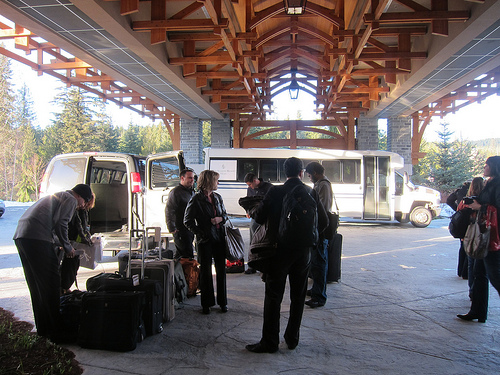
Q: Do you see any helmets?
A: No, there are no helmets.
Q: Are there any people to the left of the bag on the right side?
A: Yes, there is a person to the left of the bag.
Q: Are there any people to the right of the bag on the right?
A: No, the person is to the left of the bag.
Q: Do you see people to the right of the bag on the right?
A: No, the person is to the left of the bag.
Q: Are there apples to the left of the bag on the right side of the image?
A: No, there is a person to the left of the bag.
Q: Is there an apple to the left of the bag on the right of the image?
A: No, there is a person to the left of the bag.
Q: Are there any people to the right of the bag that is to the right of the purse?
A: Yes, there is a person to the right of the backpack.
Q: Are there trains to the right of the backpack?
A: No, there is a person to the right of the backpack.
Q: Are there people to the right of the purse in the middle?
A: Yes, there is a person to the right of the purse.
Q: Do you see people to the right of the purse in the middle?
A: Yes, there is a person to the right of the purse.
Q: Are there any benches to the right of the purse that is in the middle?
A: No, there is a person to the right of the purse.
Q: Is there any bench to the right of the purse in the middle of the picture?
A: No, there is a person to the right of the purse.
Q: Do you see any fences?
A: No, there are no fences.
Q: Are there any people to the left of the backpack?
A: Yes, there is a person to the left of the backpack.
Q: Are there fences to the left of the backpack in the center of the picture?
A: No, there is a person to the left of the backpack.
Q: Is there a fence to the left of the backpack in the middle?
A: No, there is a person to the left of the backpack.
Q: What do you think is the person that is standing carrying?
A: The person is carrying a purse.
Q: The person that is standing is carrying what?
A: The person is carrying a purse.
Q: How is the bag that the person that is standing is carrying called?
A: The bag is a purse.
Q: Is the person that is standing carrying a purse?
A: Yes, the person is carrying a purse.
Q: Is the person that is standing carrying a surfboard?
A: No, the person is carrying a purse.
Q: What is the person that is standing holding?
A: The person is holding the purse.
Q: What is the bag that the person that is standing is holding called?
A: The bag is a purse.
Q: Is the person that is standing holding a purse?
A: Yes, the person is holding a purse.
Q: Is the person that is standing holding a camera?
A: No, the person is holding a purse.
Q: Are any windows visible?
A: Yes, there is a window.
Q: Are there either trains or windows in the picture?
A: Yes, there is a window.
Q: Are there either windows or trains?
A: Yes, there is a window.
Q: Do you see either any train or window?
A: Yes, there is a window.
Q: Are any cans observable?
A: No, there are no cans.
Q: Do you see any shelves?
A: No, there are no shelves.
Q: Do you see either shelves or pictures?
A: No, there are no shelves or pictures.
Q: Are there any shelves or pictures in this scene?
A: No, there are no shelves or pictures.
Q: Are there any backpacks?
A: Yes, there is a backpack.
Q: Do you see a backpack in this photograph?
A: Yes, there is a backpack.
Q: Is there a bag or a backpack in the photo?
A: Yes, there is a backpack.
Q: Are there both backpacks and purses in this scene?
A: Yes, there are both a backpack and a purse.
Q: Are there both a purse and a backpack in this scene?
A: Yes, there are both a backpack and a purse.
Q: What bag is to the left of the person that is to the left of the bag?
A: The bag is a backpack.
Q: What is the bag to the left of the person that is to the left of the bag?
A: The bag is a backpack.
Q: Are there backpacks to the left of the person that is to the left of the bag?
A: Yes, there is a backpack to the left of the person.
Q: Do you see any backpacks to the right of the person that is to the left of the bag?
A: No, the backpack is to the left of the person.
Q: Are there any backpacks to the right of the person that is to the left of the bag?
A: No, the backpack is to the left of the person.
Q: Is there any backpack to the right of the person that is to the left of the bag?
A: No, the backpack is to the left of the person.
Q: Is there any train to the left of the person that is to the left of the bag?
A: No, there is a backpack to the left of the person.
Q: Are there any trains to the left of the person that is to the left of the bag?
A: No, there is a backpack to the left of the person.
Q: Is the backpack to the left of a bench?
A: No, the backpack is to the left of the person.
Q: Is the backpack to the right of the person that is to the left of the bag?
A: No, the backpack is to the left of the person.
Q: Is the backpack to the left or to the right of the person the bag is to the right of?
A: The backpack is to the left of the person.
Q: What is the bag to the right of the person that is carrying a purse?
A: The bag is a backpack.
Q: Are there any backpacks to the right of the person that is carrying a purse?
A: Yes, there is a backpack to the right of the person.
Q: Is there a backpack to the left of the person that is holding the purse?
A: No, the backpack is to the right of the person.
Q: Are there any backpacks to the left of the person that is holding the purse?
A: No, the backpack is to the right of the person.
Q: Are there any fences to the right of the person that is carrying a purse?
A: No, there is a backpack to the right of the person.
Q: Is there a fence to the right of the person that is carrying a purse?
A: No, there is a backpack to the right of the person.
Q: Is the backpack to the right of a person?
A: Yes, the backpack is to the right of a person.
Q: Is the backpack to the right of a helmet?
A: No, the backpack is to the right of a person.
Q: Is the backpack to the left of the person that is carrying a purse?
A: No, the backpack is to the right of the person.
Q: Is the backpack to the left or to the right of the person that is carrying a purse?
A: The backpack is to the right of the person.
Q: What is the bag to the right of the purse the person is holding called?
A: The bag is a backpack.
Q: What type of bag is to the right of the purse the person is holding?
A: The bag is a backpack.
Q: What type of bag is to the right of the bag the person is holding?
A: The bag is a backpack.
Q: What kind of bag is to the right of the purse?
A: The bag is a backpack.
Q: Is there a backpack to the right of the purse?
A: Yes, there is a backpack to the right of the purse.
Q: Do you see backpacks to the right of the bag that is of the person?
A: Yes, there is a backpack to the right of the purse.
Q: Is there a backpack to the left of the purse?
A: No, the backpack is to the right of the purse.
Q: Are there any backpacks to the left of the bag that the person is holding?
A: No, the backpack is to the right of the purse.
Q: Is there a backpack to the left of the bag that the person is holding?
A: No, the backpack is to the right of the purse.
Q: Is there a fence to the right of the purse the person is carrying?
A: No, there is a backpack to the right of the purse.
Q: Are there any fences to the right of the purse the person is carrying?
A: No, there is a backpack to the right of the purse.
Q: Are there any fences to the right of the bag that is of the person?
A: No, there is a backpack to the right of the purse.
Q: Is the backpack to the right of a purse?
A: Yes, the backpack is to the right of a purse.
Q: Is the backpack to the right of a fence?
A: No, the backpack is to the right of a purse.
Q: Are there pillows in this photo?
A: No, there are no pillows.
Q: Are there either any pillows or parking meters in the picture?
A: No, there are no pillows or parking meters.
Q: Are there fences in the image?
A: No, there are no fences.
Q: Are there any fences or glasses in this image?
A: No, there are no fences or glasses.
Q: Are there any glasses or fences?
A: No, there are no fences or glasses.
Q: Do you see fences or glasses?
A: No, there are no fences or glasses.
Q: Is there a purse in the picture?
A: Yes, there is a purse.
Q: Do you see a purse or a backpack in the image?
A: Yes, there is a purse.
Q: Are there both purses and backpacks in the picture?
A: Yes, there are both a purse and a backpack.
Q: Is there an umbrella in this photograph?
A: No, there are no umbrellas.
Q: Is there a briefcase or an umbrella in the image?
A: No, there are no umbrellas or briefcases.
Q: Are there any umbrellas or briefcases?
A: No, there are no umbrellas or briefcases.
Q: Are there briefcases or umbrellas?
A: No, there are no umbrellas or briefcases.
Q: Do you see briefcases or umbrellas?
A: No, there are no umbrellas or briefcases.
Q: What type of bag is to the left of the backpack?
A: The bag is a purse.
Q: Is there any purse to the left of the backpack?
A: Yes, there is a purse to the left of the backpack.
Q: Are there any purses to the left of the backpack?
A: Yes, there is a purse to the left of the backpack.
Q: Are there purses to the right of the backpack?
A: No, the purse is to the left of the backpack.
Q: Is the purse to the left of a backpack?
A: Yes, the purse is to the left of a backpack.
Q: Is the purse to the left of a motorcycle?
A: No, the purse is to the left of a backpack.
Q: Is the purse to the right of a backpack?
A: No, the purse is to the left of a backpack.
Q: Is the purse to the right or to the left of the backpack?
A: The purse is to the left of the backpack.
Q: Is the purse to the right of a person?
A: Yes, the purse is to the right of a person.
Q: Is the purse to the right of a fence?
A: No, the purse is to the right of a person.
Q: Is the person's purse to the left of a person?
A: No, the purse is to the right of a person.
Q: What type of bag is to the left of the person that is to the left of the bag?
A: The bag is a purse.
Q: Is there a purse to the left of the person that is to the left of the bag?
A: Yes, there is a purse to the left of the person.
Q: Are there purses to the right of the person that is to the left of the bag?
A: No, the purse is to the left of the person.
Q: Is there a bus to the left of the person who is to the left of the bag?
A: No, there is a purse to the left of the person.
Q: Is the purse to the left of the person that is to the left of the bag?
A: Yes, the purse is to the left of the person.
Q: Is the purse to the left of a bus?
A: No, the purse is to the left of the person.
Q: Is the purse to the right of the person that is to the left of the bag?
A: No, the purse is to the left of the person.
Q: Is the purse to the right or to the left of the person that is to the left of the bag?
A: The purse is to the left of the person.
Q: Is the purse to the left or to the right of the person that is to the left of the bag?
A: The purse is to the left of the person.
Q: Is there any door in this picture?
A: Yes, there is a door.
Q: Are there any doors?
A: Yes, there is a door.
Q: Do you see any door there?
A: Yes, there is a door.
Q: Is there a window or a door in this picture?
A: Yes, there is a door.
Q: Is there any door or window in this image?
A: Yes, there is a door.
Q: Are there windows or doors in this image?
A: Yes, there is a door.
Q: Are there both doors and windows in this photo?
A: Yes, there are both a door and a window.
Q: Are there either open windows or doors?
A: Yes, there is an open door.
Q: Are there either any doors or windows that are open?
A: Yes, the door is open.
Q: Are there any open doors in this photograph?
A: Yes, there is an open door.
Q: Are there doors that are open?
A: Yes, there is a door that is open.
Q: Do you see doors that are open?
A: Yes, there is a door that is open.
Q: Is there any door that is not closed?
A: Yes, there is a open door.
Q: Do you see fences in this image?
A: No, there are no fences.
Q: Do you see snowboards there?
A: No, there are no snowboards.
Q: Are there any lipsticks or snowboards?
A: No, there are no snowboards or lipsticks.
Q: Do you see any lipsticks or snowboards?
A: No, there are no snowboards or lipsticks.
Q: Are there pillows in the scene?
A: No, there are no pillows.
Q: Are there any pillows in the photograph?
A: No, there are no pillows.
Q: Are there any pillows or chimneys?
A: No, there are no pillows or chimneys.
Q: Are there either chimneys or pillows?
A: No, there are no pillows or chimneys.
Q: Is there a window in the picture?
A: Yes, there is a window.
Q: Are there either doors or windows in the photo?
A: Yes, there is a window.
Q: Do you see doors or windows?
A: Yes, there is a window.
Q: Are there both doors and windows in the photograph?
A: Yes, there are both a window and doors.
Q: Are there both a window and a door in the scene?
A: Yes, there are both a window and a door.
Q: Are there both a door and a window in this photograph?
A: Yes, there are both a window and a door.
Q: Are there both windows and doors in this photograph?
A: Yes, there are both a window and doors.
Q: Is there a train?
A: No, there are no trains.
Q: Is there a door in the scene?
A: Yes, there are doors.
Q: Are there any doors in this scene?
A: Yes, there are doors.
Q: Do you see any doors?
A: Yes, there are doors.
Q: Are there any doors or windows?
A: Yes, there are doors.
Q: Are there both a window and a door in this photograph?
A: Yes, there are both a door and a window.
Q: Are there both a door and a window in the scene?
A: Yes, there are both a door and a window.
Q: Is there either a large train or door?
A: Yes, there are large doors.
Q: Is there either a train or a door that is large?
A: Yes, the doors are large.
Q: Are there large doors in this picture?
A: Yes, there are large doors.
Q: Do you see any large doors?
A: Yes, there are large doors.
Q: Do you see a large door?
A: Yes, there are large doors.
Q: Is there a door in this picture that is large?
A: Yes, there are doors that are large.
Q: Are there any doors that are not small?
A: Yes, there are large doors.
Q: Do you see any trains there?
A: No, there are no trains.